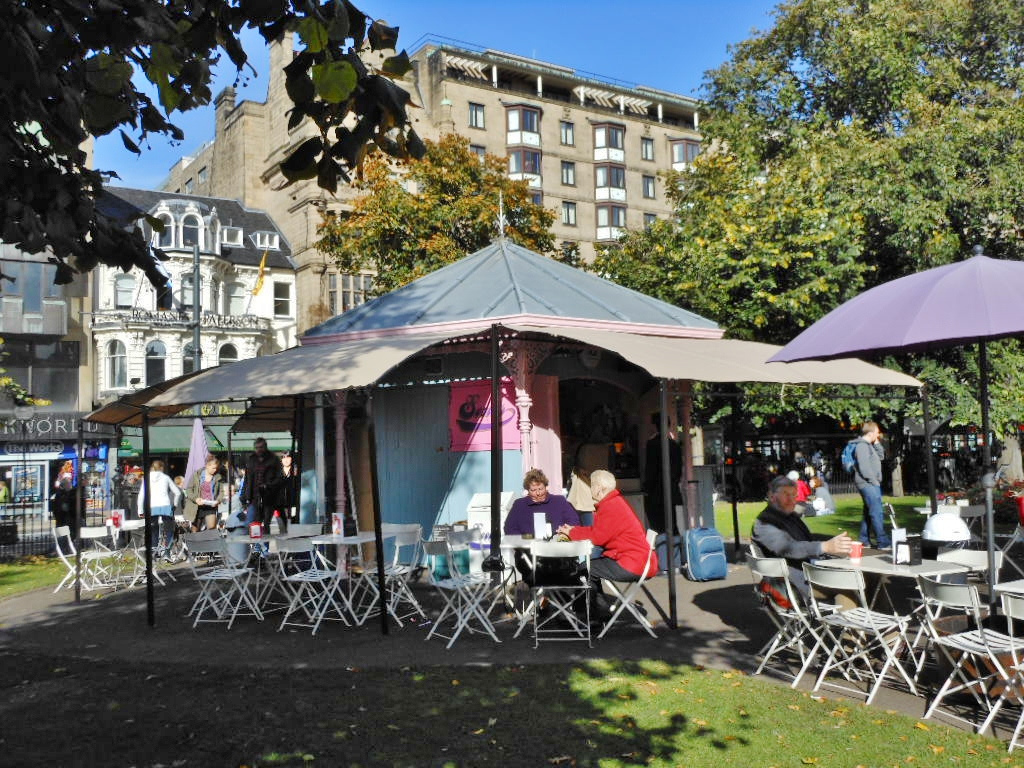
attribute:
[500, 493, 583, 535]
jacket — purple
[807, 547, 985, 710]
table — outdoor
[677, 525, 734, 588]
backpack — blue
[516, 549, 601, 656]
chair — white, folding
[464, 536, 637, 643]
table — outdoor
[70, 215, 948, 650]
building — outdoor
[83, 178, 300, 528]
townhouse — white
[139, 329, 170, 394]
window — arched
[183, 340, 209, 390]
window — arched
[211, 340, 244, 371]
window — arched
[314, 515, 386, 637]
table — empty, white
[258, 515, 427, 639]
chairs — empty, white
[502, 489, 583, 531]
shirt — purple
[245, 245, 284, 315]
flag — yellow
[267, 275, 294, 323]
window — glass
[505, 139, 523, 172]
window — glass